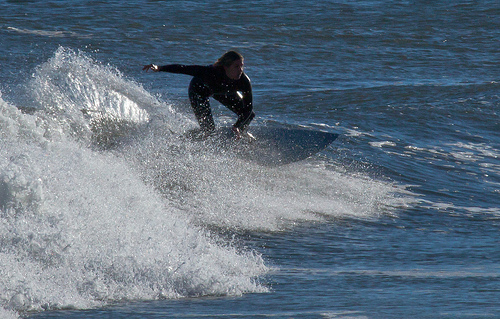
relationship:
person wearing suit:
[143, 52, 258, 148] [157, 65, 256, 140]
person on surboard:
[143, 52, 258, 148] [188, 125, 340, 168]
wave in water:
[3, 103, 177, 303] [0, 1, 499, 316]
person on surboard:
[143, 51, 258, 142] [188, 125, 340, 168]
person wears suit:
[143, 51, 258, 142] [157, 65, 256, 140]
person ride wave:
[143, 51, 258, 142] [3, 103, 177, 303]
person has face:
[143, 51, 258, 142] [224, 53, 244, 82]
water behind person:
[0, 1, 499, 316] [143, 51, 258, 142]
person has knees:
[143, 51, 258, 142] [200, 108, 255, 135]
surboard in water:
[188, 125, 340, 168] [0, 1, 499, 316]